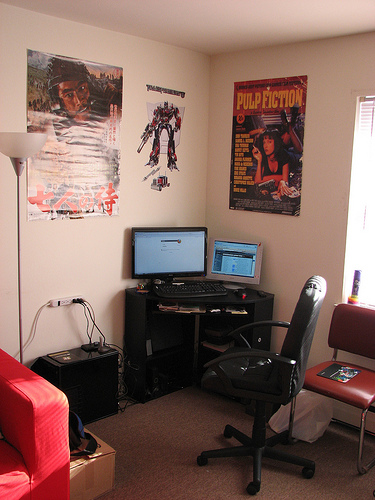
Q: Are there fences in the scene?
A: No, there are no fences.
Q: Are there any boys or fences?
A: No, there are no fences or boys.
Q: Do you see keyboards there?
A: Yes, there is a keyboard.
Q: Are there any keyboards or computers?
A: Yes, there is a keyboard.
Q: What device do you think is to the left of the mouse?
A: The device is a keyboard.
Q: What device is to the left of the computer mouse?
A: The device is a keyboard.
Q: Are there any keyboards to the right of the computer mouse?
A: No, the keyboard is to the left of the computer mouse.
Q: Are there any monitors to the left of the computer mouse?
A: No, there is a keyboard to the left of the computer mouse.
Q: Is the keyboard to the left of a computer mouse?
A: Yes, the keyboard is to the left of a computer mouse.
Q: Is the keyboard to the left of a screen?
A: No, the keyboard is to the left of the chair.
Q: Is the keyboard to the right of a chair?
A: No, the keyboard is to the left of a chair.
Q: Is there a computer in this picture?
A: Yes, there is a computer.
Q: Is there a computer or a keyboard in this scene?
A: Yes, there is a computer.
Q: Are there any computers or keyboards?
A: Yes, there is a computer.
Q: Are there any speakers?
A: No, there are no speakers.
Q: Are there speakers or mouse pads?
A: No, there are no speakers or mouse pads.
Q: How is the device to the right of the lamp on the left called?
A: The device is a computer.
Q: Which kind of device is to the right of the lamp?
A: The device is a computer.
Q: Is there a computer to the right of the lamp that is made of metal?
A: Yes, there is a computer to the right of the lamp.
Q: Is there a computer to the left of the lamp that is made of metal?
A: No, the computer is to the right of the lamp.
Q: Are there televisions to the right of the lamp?
A: No, there is a computer to the right of the lamp.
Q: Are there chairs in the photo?
A: Yes, there is a chair.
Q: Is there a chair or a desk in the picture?
A: Yes, there is a chair.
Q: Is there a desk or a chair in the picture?
A: Yes, there is a chair.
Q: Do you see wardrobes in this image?
A: No, there are no wardrobes.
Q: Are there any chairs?
A: Yes, there is a chair.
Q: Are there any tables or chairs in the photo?
A: Yes, there is a chair.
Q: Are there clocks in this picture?
A: No, there are no clocks.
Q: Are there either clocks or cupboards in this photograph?
A: No, there are no clocks or cupboards.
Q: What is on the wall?
A: The poster is on the wall.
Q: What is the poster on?
A: The poster is on the wall.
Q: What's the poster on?
A: The poster is on the wall.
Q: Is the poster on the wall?
A: Yes, the poster is on the wall.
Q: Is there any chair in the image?
A: Yes, there is a chair.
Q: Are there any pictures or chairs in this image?
A: Yes, there is a chair.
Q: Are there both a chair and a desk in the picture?
A: Yes, there are both a chair and a desk.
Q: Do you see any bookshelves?
A: No, there are no bookshelves.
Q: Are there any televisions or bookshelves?
A: No, there are no bookshelves or televisions.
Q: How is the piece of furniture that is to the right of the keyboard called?
A: The piece of furniture is a chair.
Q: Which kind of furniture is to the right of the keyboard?
A: The piece of furniture is a chair.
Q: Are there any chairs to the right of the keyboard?
A: Yes, there is a chair to the right of the keyboard.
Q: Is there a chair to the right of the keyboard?
A: Yes, there is a chair to the right of the keyboard.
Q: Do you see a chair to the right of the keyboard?
A: Yes, there is a chair to the right of the keyboard.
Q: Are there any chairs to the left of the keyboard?
A: No, the chair is to the right of the keyboard.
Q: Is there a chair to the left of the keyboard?
A: No, the chair is to the right of the keyboard.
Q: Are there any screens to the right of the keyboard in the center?
A: No, there is a chair to the right of the keyboard.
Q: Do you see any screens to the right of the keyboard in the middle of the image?
A: No, there is a chair to the right of the keyboard.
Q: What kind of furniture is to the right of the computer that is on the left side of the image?
A: The piece of furniture is a chair.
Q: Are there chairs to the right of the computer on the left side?
A: Yes, there is a chair to the right of the computer.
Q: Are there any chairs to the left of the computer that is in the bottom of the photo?
A: No, the chair is to the right of the computer.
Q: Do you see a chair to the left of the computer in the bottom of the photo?
A: No, the chair is to the right of the computer.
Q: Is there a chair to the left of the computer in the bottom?
A: No, the chair is to the right of the computer.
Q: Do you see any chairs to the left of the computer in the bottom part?
A: No, the chair is to the right of the computer.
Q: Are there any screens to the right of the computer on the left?
A: No, there is a chair to the right of the computer.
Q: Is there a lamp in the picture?
A: Yes, there is a lamp.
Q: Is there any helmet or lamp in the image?
A: Yes, there is a lamp.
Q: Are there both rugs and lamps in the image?
A: No, there is a lamp but no rugs.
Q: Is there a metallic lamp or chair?
A: Yes, there is a metal lamp.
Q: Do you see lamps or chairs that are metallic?
A: Yes, the lamp is metallic.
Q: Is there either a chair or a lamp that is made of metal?
A: Yes, the lamp is made of metal.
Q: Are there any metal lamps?
A: Yes, there is a metal lamp.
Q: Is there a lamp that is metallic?
A: Yes, there is a lamp that is metallic.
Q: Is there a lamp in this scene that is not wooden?
A: Yes, there is a metallic lamp.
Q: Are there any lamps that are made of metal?
A: Yes, there is a lamp that is made of metal.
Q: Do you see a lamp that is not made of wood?
A: Yes, there is a lamp that is made of metal.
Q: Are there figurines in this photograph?
A: No, there are no figurines.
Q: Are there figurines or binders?
A: No, there are no figurines or binders.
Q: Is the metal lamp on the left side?
A: Yes, the lamp is on the left of the image.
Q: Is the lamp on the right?
A: No, the lamp is on the left of the image.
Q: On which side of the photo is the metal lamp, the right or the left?
A: The lamp is on the left of the image.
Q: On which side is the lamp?
A: The lamp is on the left of the image.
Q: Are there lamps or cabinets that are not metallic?
A: No, there is a lamp but it is metallic.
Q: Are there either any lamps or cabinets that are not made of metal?
A: No, there is a lamp but it is made of metal.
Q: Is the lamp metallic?
A: Yes, the lamp is metallic.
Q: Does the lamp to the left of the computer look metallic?
A: Yes, the lamp is metallic.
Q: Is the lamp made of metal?
A: Yes, the lamp is made of metal.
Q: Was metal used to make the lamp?
A: Yes, the lamp is made of metal.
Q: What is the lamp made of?
A: The lamp is made of metal.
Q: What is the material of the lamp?
A: The lamp is made of metal.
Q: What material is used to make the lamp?
A: The lamp is made of metal.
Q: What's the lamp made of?
A: The lamp is made of metal.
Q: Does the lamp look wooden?
A: No, the lamp is metallic.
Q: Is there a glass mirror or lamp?
A: No, there is a lamp but it is metallic.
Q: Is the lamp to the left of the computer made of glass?
A: No, the lamp is made of metal.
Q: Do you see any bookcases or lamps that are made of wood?
A: No, there is a lamp but it is made of metal.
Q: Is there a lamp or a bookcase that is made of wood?
A: No, there is a lamp but it is made of metal.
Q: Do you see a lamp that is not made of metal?
A: No, there is a lamp but it is made of metal.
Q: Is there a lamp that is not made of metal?
A: No, there is a lamp but it is made of metal.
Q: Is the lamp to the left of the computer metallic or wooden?
A: The lamp is metallic.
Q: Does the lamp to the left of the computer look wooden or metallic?
A: The lamp is metallic.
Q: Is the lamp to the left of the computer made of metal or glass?
A: The lamp is made of metal.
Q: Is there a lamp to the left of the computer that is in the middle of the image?
A: Yes, there is a lamp to the left of the computer.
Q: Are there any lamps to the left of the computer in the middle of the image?
A: Yes, there is a lamp to the left of the computer.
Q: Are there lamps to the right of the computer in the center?
A: No, the lamp is to the left of the computer.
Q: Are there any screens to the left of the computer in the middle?
A: No, there is a lamp to the left of the computer.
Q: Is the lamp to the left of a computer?
A: Yes, the lamp is to the left of a computer.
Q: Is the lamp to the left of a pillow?
A: No, the lamp is to the left of a computer.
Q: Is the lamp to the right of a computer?
A: No, the lamp is to the left of a computer.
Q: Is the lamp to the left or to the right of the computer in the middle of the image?
A: The lamp is to the left of the computer.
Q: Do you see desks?
A: Yes, there is a desk.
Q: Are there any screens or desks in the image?
A: Yes, there is a desk.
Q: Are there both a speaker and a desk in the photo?
A: No, there is a desk but no speakers.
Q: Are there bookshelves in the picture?
A: No, there are no bookshelves.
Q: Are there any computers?
A: Yes, there is a computer.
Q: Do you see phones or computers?
A: Yes, there is a computer.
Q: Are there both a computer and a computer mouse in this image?
A: Yes, there are both a computer and a computer mouse.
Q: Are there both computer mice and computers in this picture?
A: Yes, there are both a computer and a computer mouse.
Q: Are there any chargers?
A: No, there are no chargers.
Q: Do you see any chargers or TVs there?
A: No, there are no chargers or tvs.